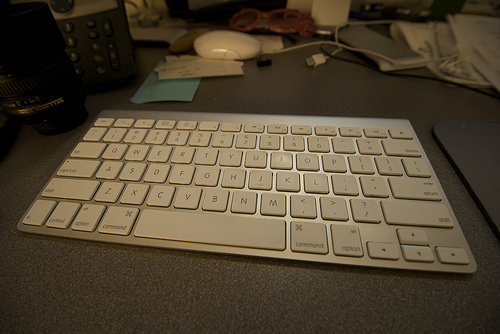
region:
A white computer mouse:
[200, 26, 260, 68]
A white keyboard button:
[435, 237, 465, 267]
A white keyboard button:
[367, 240, 407, 258]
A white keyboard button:
[331, 216, 378, 256]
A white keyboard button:
[291, 219, 332, 251]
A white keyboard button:
[138, 204, 290, 242]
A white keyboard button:
[118, 159, 146, 177]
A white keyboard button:
[245, 156, 272, 190]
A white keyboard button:
[290, 152, 318, 172]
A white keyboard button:
[101, 203, 136, 237]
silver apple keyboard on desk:
[15, 70, 490, 291]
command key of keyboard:
[287, 217, 329, 258]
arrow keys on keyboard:
[365, 222, 471, 273]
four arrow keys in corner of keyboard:
[365, 223, 483, 287]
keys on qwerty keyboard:
[101, 138, 246, 170]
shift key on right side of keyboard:
[378, 193, 454, 233]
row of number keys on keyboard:
[100, 123, 350, 162]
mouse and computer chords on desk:
[191, 24, 363, 99]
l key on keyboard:
[300, 169, 331, 198]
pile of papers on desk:
[381, 1, 498, 118]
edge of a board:
[278, 258, 307, 290]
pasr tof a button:
[284, 233, 301, 268]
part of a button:
[232, 202, 264, 259]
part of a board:
[259, 133, 284, 175]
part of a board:
[81, 89, 130, 168]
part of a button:
[254, 206, 299, 283]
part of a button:
[299, 191, 319, 243]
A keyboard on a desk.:
[16, 105, 478, 275]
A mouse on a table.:
[193, 28, 263, 62]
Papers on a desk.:
[128, 52, 244, 104]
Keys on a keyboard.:
[16, 106, 479, 275]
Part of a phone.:
[48, 0, 141, 95]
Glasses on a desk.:
[226, 6, 307, 34]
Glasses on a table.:
[228, 6, 316, 35]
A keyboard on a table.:
[16, 108, 479, 277]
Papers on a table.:
[126, 50, 245, 105]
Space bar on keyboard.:
[131, 206, 286, 251]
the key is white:
[102, 144, 123, 159]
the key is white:
[127, 143, 148, 162]